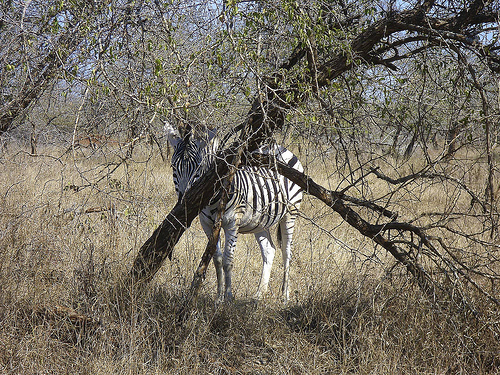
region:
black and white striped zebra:
[108, 112, 315, 305]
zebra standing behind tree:
[163, 107, 313, 301]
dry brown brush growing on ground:
[27, 169, 312, 372]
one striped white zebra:
[148, 117, 309, 297]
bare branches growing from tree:
[326, 157, 491, 261]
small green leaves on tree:
[81, 11, 345, 143]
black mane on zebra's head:
[166, 101, 202, 166]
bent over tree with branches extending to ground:
[106, 13, 496, 282]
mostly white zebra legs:
[202, 210, 328, 312]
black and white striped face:
[166, 125, 223, 220]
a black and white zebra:
[161, 116, 304, 307]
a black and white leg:
[203, 216, 225, 311]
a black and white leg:
[224, 217, 235, 301]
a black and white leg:
[255, 223, 273, 295]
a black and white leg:
[280, 212, 293, 301]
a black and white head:
[168, 136, 208, 206]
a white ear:
[162, 121, 175, 148]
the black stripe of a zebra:
[244, 162, 258, 214]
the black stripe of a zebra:
[265, 158, 281, 219]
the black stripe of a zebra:
[283, 149, 308, 200]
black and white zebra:
[135, 96, 340, 306]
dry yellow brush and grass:
[5, 65, 170, 365]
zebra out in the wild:
[95, 75, 455, 345]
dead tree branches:
[310, 160, 490, 350]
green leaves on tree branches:
[25, 0, 360, 115]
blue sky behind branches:
[30, 5, 345, 101]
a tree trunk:
[81, 55, 391, 345]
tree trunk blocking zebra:
[91, 50, 411, 351]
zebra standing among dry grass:
[110, 68, 395, 323]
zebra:
[161, 121, 309, 284]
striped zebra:
[167, 122, 289, 282]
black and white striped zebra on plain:
[153, 118, 294, 298]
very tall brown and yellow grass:
[21, 225, 108, 327]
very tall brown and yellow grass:
[149, 308, 286, 353]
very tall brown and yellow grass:
[302, 263, 390, 349]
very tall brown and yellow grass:
[3, 206, 100, 270]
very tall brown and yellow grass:
[109, 177, 159, 219]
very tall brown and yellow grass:
[22, 163, 62, 200]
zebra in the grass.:
[157, 114, 310, 294]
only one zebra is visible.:
[154, 111, 306, 291]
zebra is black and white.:
[150, 112, 312, 309]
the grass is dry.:
[7, 130, 496, 373]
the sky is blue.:
[47, 5, 490, 133]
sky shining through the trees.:
[1, 2, 495, 152]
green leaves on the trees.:
[0, 3, 497, 143]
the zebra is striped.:
[159, 112, 306, 293]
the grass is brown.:
[2, 140, 499, 365]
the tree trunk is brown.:
[131, 137, 251, 289]